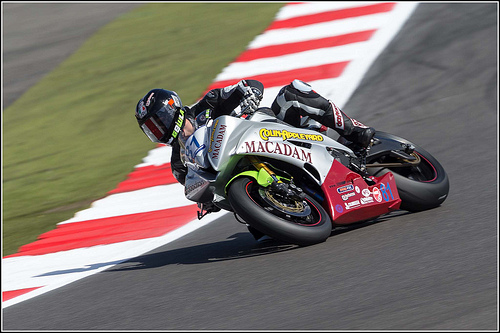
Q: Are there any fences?
A: No, there are no fences.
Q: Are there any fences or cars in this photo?
A: No, there are no fences or cars.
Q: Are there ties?
A: No, there are no ties.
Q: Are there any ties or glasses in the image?
A: No, there are no ties or glasses.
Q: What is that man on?
A: The man is on the motorbike.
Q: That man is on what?
A: The man is on the motorbike.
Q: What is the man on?
A: The man is on the motorbike.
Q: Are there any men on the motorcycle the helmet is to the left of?
A: Yes, there is a man on the motorbike.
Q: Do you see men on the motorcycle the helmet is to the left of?
A: Yes, there is a man on the motorbike.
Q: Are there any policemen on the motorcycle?
A: No, there is a man on the motorcycle.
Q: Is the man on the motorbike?
A: Yes, the man is on the motorbike.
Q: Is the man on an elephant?
A: No, the man is on the motorbike.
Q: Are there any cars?
A: No, there are no cars.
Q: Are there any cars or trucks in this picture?
A: No, there are no cars or trucks.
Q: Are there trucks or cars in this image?
A: No, there are no cars or trucks.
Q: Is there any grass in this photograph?
A: Yes, there is grass.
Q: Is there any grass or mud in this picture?
A: Yes, there is grass.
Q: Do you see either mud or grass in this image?
A: Yes, there is grass.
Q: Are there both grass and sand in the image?
A: No, there is grass but no sand.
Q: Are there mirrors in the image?
A: No, there are no mirrors.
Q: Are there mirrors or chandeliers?
A: No, there are no mirrors or chandeliers.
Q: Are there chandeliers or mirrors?
A: No, there are no mirrors or chandeliers.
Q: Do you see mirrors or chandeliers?
A: No, there are no mirrors or chandeliers.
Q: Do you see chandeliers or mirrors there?
A: No, there are no mirrors or chandeliers.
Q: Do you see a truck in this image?
A: No, there are no trucks.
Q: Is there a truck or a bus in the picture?
A: No, there are no trucks or buses.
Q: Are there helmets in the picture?
A: Yes, there is a helmet.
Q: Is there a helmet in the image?
A: Yes, there is a helmet.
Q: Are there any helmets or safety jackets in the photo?
A: Yes, there is a helmet.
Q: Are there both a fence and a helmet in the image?
A: No, there is a helmet but no fences.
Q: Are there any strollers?
A: No, there are no strollers.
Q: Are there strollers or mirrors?
A: No, there are no strollers or mirrors.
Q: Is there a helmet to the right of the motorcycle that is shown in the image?
A: No, the helmet is to the left of the motorcycle.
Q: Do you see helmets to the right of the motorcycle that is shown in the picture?
A: No, the helmet is to the left of the motorcycle.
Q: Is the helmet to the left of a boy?
A: No, the helmet is to the left of a motorcycle.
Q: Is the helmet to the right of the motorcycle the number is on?
A: No, the helmet is to the left of the motorcycle.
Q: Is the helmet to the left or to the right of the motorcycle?
A: The helmet is to the left of the motorcycle.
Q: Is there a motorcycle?
A: Yes, there is a motorcycle.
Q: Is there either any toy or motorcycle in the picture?
A: Yes, there is a motorcycle.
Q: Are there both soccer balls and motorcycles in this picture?
A: No, there is a motorcycle but no soccer balls.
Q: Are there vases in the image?
A: No, there are no vases.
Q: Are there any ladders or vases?
A: No, there are no vases or ladders.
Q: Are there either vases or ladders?
A: No, there are no vases or ladders.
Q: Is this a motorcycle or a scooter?
A: This is a motorcycle.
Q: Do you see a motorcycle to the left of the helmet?
A: No, the motorcycle is to the right of the helmet.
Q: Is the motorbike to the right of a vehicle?
A: No, the motorbike is to the right of the helmet.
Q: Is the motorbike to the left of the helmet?
A: No, the motorbike is to the right of the helmet.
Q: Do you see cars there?
A: No, there are no cars.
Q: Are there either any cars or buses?
A: No, there are no cars or buses.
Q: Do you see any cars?
A: No, there are no cars.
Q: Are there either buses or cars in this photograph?
A: No, there are no cars or buses.